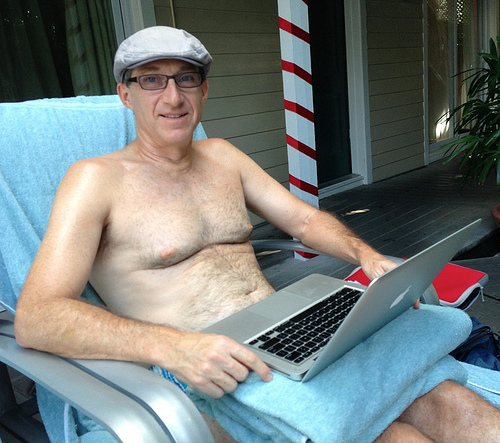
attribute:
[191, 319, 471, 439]
blanket — folded, Blue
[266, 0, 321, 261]
beam — white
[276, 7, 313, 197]
stripes — red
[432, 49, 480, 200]
plant — green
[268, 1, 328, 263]
post — white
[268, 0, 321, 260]
stripes — red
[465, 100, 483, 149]
leaves — green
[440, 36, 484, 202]
plant — outdoor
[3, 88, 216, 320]
towel — blue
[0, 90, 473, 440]
chairs — man's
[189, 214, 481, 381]
computer — silver, metal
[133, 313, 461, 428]
lap — man's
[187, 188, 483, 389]
laptop — computer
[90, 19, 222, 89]
cap — man's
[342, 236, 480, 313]
case — red, gray, zippered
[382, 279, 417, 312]
logo — apple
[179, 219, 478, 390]
computer — man's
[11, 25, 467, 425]
man — content, shirtless, relaxing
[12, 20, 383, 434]
man — shirtless, sitting down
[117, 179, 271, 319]
chest — bare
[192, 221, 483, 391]
laptop — apple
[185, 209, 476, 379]
laptop — folded, blue, silver, apple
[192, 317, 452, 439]
lap — his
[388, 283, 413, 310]
logo — Apple brand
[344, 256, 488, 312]
computer case — red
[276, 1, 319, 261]
pole — white, red, striped, like candy cane 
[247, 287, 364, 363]
keyboard — black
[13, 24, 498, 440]
man — shirtless, looking at camera, sitting, happy, without a shirt, blue eyed, smiling, seated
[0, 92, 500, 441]
towel — blue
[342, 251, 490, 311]
laptop case — red, gray